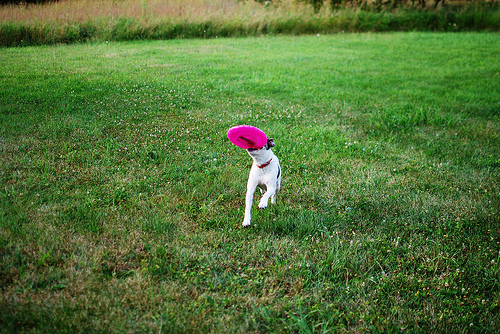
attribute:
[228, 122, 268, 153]
frisbee — pink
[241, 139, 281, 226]
dog — white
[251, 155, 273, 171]
collar — red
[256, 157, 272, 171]
collar — red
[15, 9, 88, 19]
weeds — brown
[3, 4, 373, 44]
grass — tall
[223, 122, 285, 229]
dog — small, white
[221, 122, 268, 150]
frisbee — pink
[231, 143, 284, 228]
dog — white, small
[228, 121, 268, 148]
frisbee — pink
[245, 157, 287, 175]
collar — red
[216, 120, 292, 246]
dog — small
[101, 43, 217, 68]
spots — bald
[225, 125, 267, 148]
frisbee — upside down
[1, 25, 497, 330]
grass — green